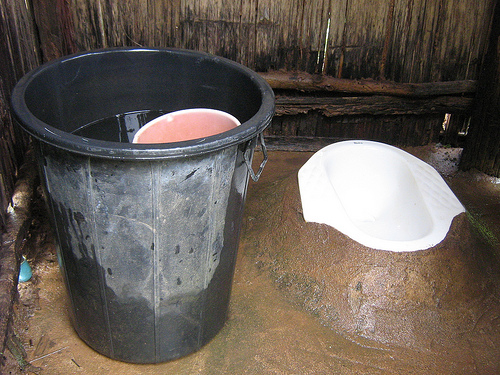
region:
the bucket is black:
[14, 42, 279, 362]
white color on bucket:
[33, 145, 253, 308]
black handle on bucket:
[242, 131, 273, 184]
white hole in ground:
[286, 134, 467, 253]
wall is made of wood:
[2, 0, 496, 372]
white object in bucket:
[127, 107, 245, 147]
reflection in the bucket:
[109, 106, 154, 143]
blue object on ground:
[17, 254, 37, 281]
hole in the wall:
[437, 110, 454, 134]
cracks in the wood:
[316, 14, 331, 75]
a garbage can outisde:
[27, 47, 339, 363]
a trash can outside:
[14, 66, 379, 360]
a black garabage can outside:
[21, 41, 293, 362]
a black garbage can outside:
[64, 16, 312, 355]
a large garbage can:
[46, 14, 315, 363]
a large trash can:
[47, 32, 272, 366]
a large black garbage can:
[34, 17, 336, 373]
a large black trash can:
[36, 40, 379, 373]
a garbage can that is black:
[19, 36, 290, 363]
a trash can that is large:
[41, 43, 316, 365]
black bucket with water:
[4, 14, 291, 361]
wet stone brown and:
[291, 254, 366, 323]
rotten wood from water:
[252, 12, 486, 180]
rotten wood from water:
[271, 64, 403, 81]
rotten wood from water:
[265, 38, 465, 109]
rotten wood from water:
[293, 47, 360, 118]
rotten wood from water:
[255, 66, 449, 68]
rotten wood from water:
[132, 21, 451, 28]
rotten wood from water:
[446, 79, 474, 95]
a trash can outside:
[43, 45, 318, 373]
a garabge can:
[35, 11, 401, 371]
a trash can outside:
[67, 6, 289, 372]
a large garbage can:
[17, 14, 232, 374]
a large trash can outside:
[22, 40, 320, 363]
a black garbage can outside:
[26, 44, 280, 284]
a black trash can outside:
[17, 43, 339, 370]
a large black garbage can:
[29, 25, 295, 342]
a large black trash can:
[19, 18, 281, 360]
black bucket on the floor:
[8, 42, 299, 365]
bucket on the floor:
[10, 47, 280, 362]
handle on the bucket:
[244, 133, 269, 179]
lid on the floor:
[290, 134, 469, 251]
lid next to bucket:
[293, 139, 473, 249]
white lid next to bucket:
[293, 134, 468, 249]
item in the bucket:
[118, 99, 255, 151]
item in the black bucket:
[133, 106, 245, 159]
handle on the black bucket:
[239, 132, 273, 182]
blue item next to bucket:
[8, 262, 40, 283]